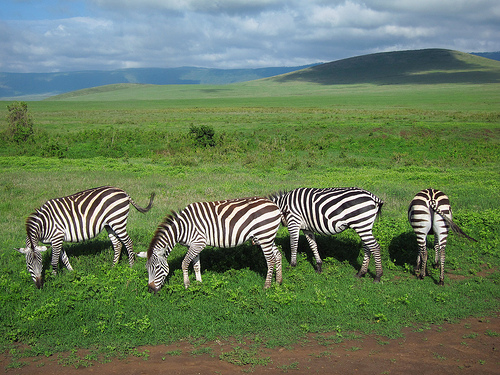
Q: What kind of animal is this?
A: Zebra.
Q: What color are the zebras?
A: Black and white.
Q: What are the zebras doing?
A: Grazing.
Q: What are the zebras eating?
A: Grass.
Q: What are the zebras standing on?
A: Grass.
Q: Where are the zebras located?
A: Field.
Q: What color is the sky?
A: Blue and white.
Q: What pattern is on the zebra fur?
A: Stripes.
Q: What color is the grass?
A: Green.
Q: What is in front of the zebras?
A: A dirt path.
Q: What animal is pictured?
A: Zebra.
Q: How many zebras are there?
A: 4.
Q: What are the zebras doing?
A: Grazing.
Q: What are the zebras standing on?
A: Grass.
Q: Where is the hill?
A: Behind the zebras.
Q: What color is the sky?
A: Blue.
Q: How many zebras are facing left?
A: 3.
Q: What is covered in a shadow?
A: The hill.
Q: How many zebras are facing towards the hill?
A: 1.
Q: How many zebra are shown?
A: 4.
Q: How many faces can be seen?
A: 2.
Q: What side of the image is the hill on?
A: Right.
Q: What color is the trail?
A: Brown.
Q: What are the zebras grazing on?
A: Grass.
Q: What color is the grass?
A: Green.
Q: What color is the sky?
A: Blue.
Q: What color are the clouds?
A: White.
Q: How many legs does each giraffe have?
A: 4.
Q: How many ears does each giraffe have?
A: 2.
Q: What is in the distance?
A: Low rolling hills.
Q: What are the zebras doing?
A: Eating.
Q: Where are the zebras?
A: On grass.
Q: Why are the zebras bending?
A: They are eating.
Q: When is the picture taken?
A: Daytime.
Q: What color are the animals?
A: Black and white.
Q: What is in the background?
A: A hill.